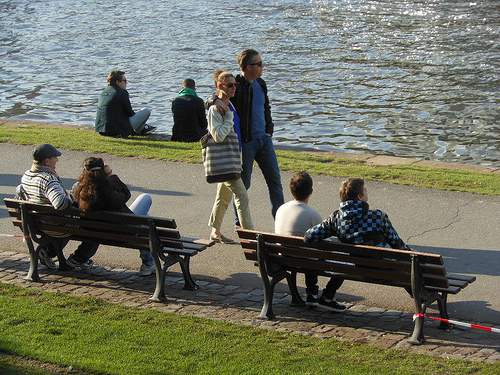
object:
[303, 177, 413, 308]
men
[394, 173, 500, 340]
beach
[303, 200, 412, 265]
sweater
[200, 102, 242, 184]
purse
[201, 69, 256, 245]
woman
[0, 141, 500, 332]
sidewalk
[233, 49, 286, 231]
man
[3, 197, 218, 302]
bench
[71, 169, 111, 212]
hair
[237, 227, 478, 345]
bench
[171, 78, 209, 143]
man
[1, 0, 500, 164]
lake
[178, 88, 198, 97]
green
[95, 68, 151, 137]
man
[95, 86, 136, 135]
jacket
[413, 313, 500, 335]
tape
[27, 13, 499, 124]
ripples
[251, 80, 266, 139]
shirt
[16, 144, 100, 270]
person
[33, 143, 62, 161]
cap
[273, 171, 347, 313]
person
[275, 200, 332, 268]
shirt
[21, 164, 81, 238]
jacket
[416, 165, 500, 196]
grass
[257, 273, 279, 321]
leg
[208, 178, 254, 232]
pants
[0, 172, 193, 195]
shadow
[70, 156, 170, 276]
people